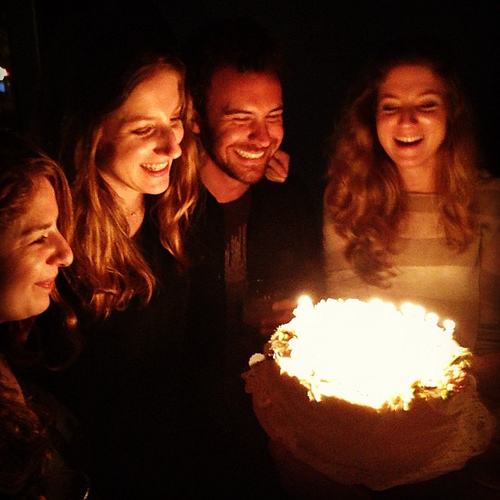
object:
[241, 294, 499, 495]
birthday cake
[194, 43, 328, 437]
man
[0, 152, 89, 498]
woman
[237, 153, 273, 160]
teeth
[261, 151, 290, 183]
hand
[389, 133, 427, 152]
mouth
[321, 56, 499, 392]
people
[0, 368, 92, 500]
shirt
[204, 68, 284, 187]
faces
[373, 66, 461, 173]
face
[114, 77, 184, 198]
face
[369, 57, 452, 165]
head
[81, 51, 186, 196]
head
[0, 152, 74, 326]
head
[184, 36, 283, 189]
head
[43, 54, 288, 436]
woman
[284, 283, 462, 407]
light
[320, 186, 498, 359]
shirt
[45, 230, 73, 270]
nose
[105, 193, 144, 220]
necklace